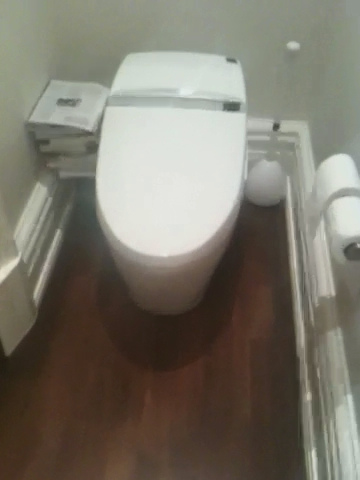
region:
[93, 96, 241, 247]
The toilet lid is down.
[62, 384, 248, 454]
The floor is wooden.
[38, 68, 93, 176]
Newspapers on the wall.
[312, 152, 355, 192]
Toilet paper on the wall.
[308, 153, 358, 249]
There are two rolls of toilet paper.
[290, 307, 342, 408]
The border is white.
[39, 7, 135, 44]
The wall is tan.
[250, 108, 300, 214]
A toilet bowl cleaner next to the toilet.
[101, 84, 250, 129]
A grey stripe on the toilet lid.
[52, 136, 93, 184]
Books under the newspaper.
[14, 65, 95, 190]
things to read stacked up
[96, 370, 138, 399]
hard wood floor there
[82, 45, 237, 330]
the toilet lid is down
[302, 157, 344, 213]
a toilet paper roll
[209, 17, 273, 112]
the bathroom is white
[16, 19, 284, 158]
a bathroom is shown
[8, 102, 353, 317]
room is white except for floor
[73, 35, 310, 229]
a white toilet in the room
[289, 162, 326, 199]
the baseboards are white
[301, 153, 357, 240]
two toilet paper rolls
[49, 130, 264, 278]
toilet.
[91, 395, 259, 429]
floor in the bathroom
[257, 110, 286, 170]
toilet cleaner next to the toilet.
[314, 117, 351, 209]
toilet paper holder.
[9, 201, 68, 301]
Baseboard trim in the bathroom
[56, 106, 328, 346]
toilet lid on toilet.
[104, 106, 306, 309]
white toilet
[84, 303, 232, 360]
wood floor in the bathroom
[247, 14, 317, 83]
the wall in the bathroom.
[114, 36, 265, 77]
back of the toilet against the wall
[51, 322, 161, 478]
Wooden floor in the bathroom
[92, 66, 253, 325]
A large white toilet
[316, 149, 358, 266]
A pair of toilet paper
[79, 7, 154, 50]
A small patch of the bathroom wall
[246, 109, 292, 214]
A white toilet brush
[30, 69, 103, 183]
A stack of newspapers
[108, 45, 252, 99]
The top of the toilet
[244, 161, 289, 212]
The base of the toilet brush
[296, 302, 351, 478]
White baseboard in bathroom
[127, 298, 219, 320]
Bottom of the toilet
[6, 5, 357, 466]
Interior shot of room.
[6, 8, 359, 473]
Bathroom view, from above.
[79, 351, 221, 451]
Dark wood floor.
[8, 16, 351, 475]
Cramped, but clean bathroom space.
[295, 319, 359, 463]
White baseboard.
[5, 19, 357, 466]
Grey walls and white baseboard, enclosing toilet and floor.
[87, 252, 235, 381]
Shadow, indicating unseen window.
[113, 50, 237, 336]
White toilet without tank, featuring closed lid.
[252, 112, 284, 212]
White toilet brush in case.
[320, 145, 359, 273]
Two, hanging rolls of toilet paper.